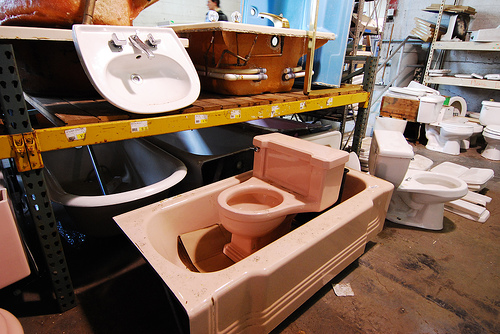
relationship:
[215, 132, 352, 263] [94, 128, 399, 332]
toilet in bath tub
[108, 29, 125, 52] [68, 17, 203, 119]
knob on sink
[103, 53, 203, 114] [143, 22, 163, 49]
sink has knob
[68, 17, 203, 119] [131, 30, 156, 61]
sink has faucet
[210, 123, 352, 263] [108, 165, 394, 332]
toilet in bathtub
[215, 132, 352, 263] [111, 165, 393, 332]
toilet in tub